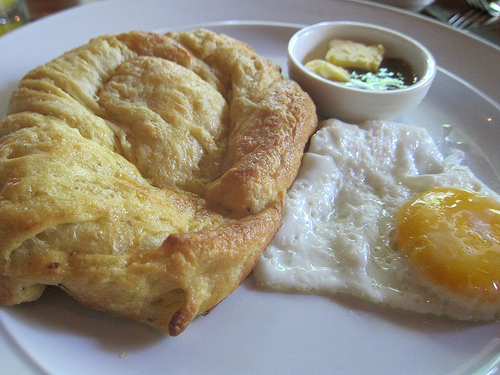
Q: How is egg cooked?
A: Fried.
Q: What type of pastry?
A: Danish.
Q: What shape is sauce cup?
A: Round.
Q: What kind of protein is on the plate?
A: Eggs.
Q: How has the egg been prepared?
A: Over easy.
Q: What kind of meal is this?
A: Breakfast.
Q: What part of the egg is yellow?
A: Yolk.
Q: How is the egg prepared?
A: Fried.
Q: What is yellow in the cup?
A: Butter.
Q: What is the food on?
A: Plate.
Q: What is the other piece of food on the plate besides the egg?
A: Pastry.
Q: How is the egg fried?
A: Soft.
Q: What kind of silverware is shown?
A: Fork.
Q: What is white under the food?
A: Plate.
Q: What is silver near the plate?
A: Fork.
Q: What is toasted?
A: Pastry.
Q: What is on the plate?
A: The food.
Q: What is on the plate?
A: Tan lemon danish.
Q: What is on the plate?
A: Tan lemon danish.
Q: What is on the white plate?
A: Tan lemon danish.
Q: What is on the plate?
A: Yellow eggs.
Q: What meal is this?
A: Breakfast.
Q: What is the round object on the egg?
A: The yolk.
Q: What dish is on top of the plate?
A: A small bowl.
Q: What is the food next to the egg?
A: A pastry.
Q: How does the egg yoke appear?
A: Rounds and yellow.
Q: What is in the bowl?
A: A sauce.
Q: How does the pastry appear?
A: Plain.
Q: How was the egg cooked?
A: Fried.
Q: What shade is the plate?
A: White.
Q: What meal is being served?
A: Breakfast.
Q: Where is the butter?
A: In cup.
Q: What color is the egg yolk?
A: Yellow.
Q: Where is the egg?
A: Beside bread.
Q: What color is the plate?
A: White.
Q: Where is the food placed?
A: On plate.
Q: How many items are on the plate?
A: 3.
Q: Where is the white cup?
A: Back of plate.